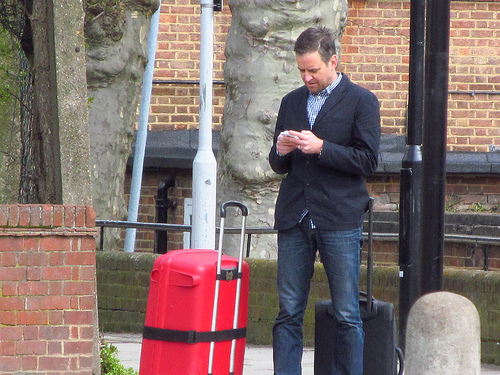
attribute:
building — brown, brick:
[127, 16, 497, 253]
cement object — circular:
[402, 290, 481, 373]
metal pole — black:
[396, 0, 424, 358]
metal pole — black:
[423, 0, 446, 297]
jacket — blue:
[268, 74, 380, 234]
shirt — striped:
[307, 73, 344, 130]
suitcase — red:
[75, 199, 296, 369]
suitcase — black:
[318, 300, 399, 373]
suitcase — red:
[133, 196, 250, 371]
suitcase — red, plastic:
[151, 242, 246, 374]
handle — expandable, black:
[351, 188, 389, 302]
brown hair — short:
[293, 26, 338, 65]